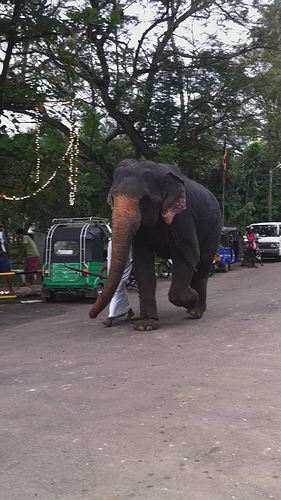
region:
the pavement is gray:
[29, 363, 237, 463]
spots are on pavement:
[11, 364, 107, 414]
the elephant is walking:
[108, 162, 235, 337]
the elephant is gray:
[110, 158, 212, 327]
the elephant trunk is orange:
[91, 194, 135, 320]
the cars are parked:
[43, 221, 124, 295]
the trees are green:
[77, 45, 278, 176]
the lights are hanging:
[30, 106, 80, 206]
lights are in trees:
[4, 101, 91, 206]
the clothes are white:
[105, 241, 130, 315]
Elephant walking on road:
[73, 147, 234, 345]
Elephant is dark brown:
[74, 143, 229, 339]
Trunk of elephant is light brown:
[84, 194, 144, 322]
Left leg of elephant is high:
[166, 242, 203, 315]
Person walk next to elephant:
[97, 213, 137, 328]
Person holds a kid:
[240, 223, 263, 268]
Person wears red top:
[240, 223, 266, 269]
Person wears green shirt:
[12, 227, 44, 289]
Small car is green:
[36, 212, 111, 307]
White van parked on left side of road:
[241, 217, 279, 257]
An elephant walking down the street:
[47, 149, 253, 370]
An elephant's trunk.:
[87, 191, 133, 324]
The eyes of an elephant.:
[96, 182, 159, 211]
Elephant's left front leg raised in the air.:
[159, 245, 211, 337]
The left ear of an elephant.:
[151, 159, 194, 232]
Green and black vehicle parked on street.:
[41, 209, 109, 304]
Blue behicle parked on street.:
[215, 219, 246, 278]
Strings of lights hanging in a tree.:
[7, 105, 102, 212]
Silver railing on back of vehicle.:
[41, 217, 94, 270]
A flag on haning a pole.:
[216, 132, 234, 232]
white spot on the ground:
[218, 336, 246, 350]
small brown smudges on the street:
[128, 416, 239, 476]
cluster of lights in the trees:
[25, 128, 106, 185]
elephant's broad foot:
[131, 317, 170, 336]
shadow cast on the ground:
[68, 305, 236, 341]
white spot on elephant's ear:
[161, 182, 195, 230]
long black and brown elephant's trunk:
[98, 190, 139, 322]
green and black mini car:
[39, 219, 126, 309]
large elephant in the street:
[64, 137, 249, 334]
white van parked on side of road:
[243, 214, 280, 262]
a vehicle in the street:
[33, 217, 114, 306]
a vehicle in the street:
[208, 221, 240, 273]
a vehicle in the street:
[243, 219, 279, 274]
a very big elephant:
[79, 153, 221, 331]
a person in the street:
[97, 224, 136, 329]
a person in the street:
[242, 226, 260, 274]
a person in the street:
[15, 229, 40, 284]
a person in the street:
[0, 222, 18, 294]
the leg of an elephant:
[176, 238, 198, 315]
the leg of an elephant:
[131, 237, 165, 337]